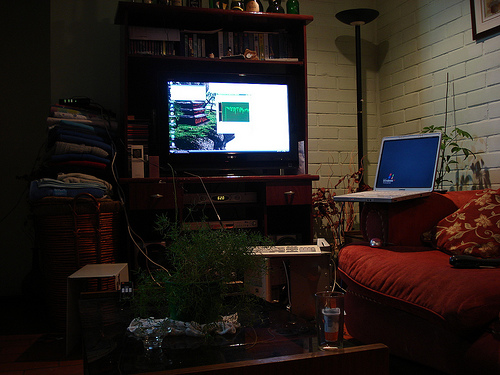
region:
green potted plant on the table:
[129, 214, 274, 327]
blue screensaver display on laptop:
[330, 122, 447, 218]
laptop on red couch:
[330, 121, 442, 218]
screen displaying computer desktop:
[149, 65, 310, 177]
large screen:
[154, 65, 305, 170]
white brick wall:
[314, 111, 359, 127]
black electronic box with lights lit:
[51, 94, 106, 107]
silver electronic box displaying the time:
[178, 189, 263, 203]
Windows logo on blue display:
[377, 169, 402, 187]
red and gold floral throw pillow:
[430, 185, 497, 259]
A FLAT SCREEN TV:
[141, 75, 313, 182]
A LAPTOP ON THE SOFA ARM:
[327, 125, 450, 214]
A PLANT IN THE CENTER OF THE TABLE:
[146, 213, 258, 335]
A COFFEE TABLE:
[64, 283, 372, 363]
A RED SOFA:
[334, 186, 496, 368]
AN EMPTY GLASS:
[305, 286, 350, 357]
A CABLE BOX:
[188, 181, 264, 211]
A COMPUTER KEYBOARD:
[234, 241, 340, 261]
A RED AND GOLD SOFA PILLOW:
[422, 180, 498, 272]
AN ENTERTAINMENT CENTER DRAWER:
[256, 180, 326, 215]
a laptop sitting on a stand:
[326, 126, 446, 223]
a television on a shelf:
[137, 64, 318, 168]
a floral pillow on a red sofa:
[431, 196, 494, 267]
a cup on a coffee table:
[319, 298, 366, 360]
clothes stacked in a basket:
[21, 94, 121, 262]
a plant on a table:
[131, 224, 256, 331]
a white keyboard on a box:
[236, 229, 351, 261]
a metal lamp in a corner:
[334, 6, 387, 185]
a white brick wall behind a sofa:
[409, 23, 481, 103]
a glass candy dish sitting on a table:
[122, 317, 182, 354]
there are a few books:
[75, 2, 320, 65]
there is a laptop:
[359, 121, 416, 248]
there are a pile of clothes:
[31, 128, 101, 205]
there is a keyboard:
[220, 237, 335, 257]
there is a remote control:
[440, 240, 499, 297]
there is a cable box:
[178, 182, 270, 214]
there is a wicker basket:
[63, 197, 132, 276]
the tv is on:
[174, 125, 303, 172]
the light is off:
[329, 4, 389, 187]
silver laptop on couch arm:
[328, 123, 495, 243]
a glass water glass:
[311, 282, 355, 358]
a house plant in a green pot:
[118, 208, 268, 353]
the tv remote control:
[443, 240, 499, 272]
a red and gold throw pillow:
[433, 165, 499, 263]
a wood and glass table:
[71, 286, 391, 371]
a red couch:
[326, 179, 498, 352]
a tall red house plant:
[310, 138, 378, 318]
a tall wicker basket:
[45, 182, 143, 334]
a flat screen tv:
[147, 57, 314, 175]